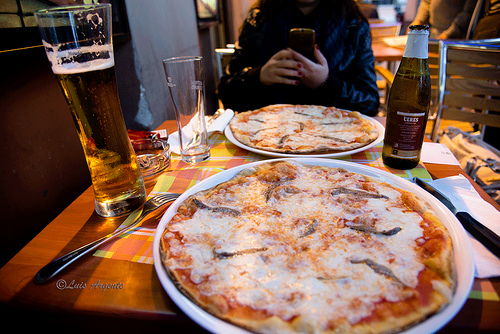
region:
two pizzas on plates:
[205, 104, 432, 332]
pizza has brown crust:
[205, 165, 448, 310]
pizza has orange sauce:
[207, 170, 437, 306]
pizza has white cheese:
[202, 194, 387, 299]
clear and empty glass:
[157, 45, 217, 170]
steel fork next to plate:
[50, 175, 190, 274]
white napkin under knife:
[431, 173, 499, 275]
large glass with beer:
[50, 14, 136, 220]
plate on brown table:
[181, 147, 429, 332]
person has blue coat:
[228, 2, 381, 114]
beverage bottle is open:
[388, 22, 428, 167]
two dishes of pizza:
[222, 107, 409, 329]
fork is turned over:
[98, 191, 178, 241]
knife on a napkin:
[412, 173, 479, 245]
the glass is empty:
[162, 57, 214, 162]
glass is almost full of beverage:
[30, 7, 141, 209]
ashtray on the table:
[130, 134, 167, 173]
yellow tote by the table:
[440, 124, 498, 196]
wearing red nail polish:
[265, 46, 328, 91]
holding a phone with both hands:
[283, 28, 322, 78]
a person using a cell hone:
[247, 23, 389, 124]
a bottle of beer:
[397, 30, 434, 179]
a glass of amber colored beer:
[32, 2, 165, 216]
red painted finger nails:
[274, 52, 344, 102]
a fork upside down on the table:
[53, 166, 183, 294]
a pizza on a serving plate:
[177, 148, 456, 332]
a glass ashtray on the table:
[132, 130, 182, 185]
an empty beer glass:
[155, 54, 245, 168]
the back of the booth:
[20, 62, 96, 249]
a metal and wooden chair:
[444, 37, 499, 109]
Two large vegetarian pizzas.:
[167, 98, 428, 333]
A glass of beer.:
[63, 73, 143, 203]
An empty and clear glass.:
[168, 78, 213, 159]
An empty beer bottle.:
[379, 73, 429, 165]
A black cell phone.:
[288, 27, 321, 69]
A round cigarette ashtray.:
[132, 139, 170, 174]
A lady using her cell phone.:
[222, 3, 374, 105]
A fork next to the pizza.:
[32, 190, 184, 286]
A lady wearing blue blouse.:
[221, 4, 378, 100]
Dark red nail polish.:
[253, 47, 348, 84]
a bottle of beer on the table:
[381, 24, 431, 169]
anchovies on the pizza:
[353, 256, 400, 283]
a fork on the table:
[31, 191, 181, 287]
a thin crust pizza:
[161, 159, 457, 331]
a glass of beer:
[36, 3, 145, 216]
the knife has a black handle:
[414, 175, 499, 253]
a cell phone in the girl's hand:
[266, 28, 324, 80]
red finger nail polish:
[289, 60, 306, 87]